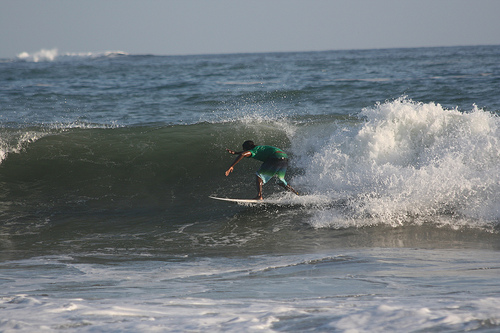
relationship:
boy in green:
[224, 140, 299, 201] [249, 142, 291, 163]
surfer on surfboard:
[223, 136, 301, 201] [207, 194, 335, 204]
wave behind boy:
[3, 96, 500, 234] [224, 140, 299, 201]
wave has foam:
[3, 96, 500, 234] [280, 93, 499, 238]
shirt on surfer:
[247, 141, 288, 163] [223, 136, 301, 201]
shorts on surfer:
[256, 153, 289, 187] [223, 136, 301, 201]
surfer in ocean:
[223, 136, 301, 201] [0, 42, 498, 332]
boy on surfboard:
[223, 138, 299, 205] [204, 189, 335, 208]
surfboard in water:
[204, 189, 335, 208] [3, 47, 499, 332]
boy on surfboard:
[224, 140, 299, 201] [204, 189, 335, 208]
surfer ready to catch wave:
[223, 136, 301, 201] [3, 96, 500, 234]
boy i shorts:
[224, 140, 299, 201] [256, 153, 289, 187]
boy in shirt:
[224, 140, 299, 201] [247, 141, 288, 163]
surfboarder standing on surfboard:
[223, 136, 298, 199] [204, 189, 335, 208]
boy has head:
[224, 140, 299, 201] [241, 136, 257, 153]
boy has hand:
[224, 140, 299, 201] [222, 163, 235, 177]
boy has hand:
[224, 140, 299, 201] [223, 145, 239, 157]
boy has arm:
[224, 140, 299, 201] [222, 145, 254, 176]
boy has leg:
[224, 140, 299, 201] [250, 153, 281, 205]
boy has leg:
[224, 140, 299, 201] [276, 154, 307, 201]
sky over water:
[0, 0, 499, 56] [3, 47, 499, 332]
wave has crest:
[3, 96, 500, 234] [4, 113, 305, 158]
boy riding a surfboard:
[224, 140, 299, 201] [204, 189, 335, 208]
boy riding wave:
[224, 140, 299, 201] [3, 96, 500, 234]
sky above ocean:
[0, 0, 499, 56] [0, 42, 498, 332]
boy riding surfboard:
[224, 140, 299, 201] [204, 189, 335, 208]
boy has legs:
[224, 140, 299, 201] [253, 153, 301, 201]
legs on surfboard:
[253, 153, 301, 201] [204, 189, 335, 208]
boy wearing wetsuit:
[224, 140, 299, 201] [247, 142, 291, 187]